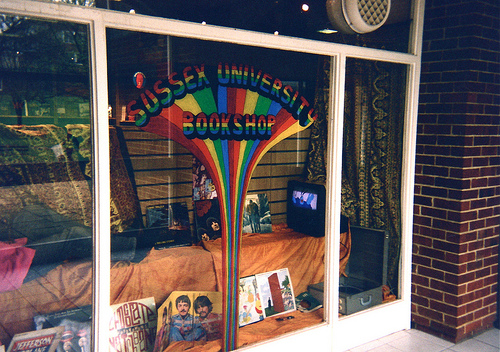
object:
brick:
[432, 132, 476, 148]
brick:
[452, 77, 487, 92]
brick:
[415, 260, 448, 280]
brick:
[410, 232, 434, 247]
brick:
[413, 301, 445, 322]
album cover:
[193, 197, 222, 244]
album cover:
[153, 290, 223, 350]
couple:
[246, 199, 260, 232]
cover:
[240, 192, 270, 234]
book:
[242, 192, 272, 236]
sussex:
[125, 64, 209, 128]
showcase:
[0, 3, 421, 351]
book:
[238, 264, 299, 327]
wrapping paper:
[123, 54, 341, 311]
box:
[306, 226, 390, 315]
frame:
[371, 34, 423, 253]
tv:
[284, 178, 325, 238]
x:
[193, 63, 214, 89]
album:
[151, 290, 231, 352]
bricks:
[458, 59, 496, 75]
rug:
[1, 117, 145, 252]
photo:
[157, 294, 227, 349]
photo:
[255, 267, 296, 319]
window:
[336, 53, 405, 318]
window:
[100, 21, 330, 350]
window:
[29, 0, 415, 53]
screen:
[293, 190, 316, 209]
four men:
[155, 293, 223, 349]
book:
[153, 280, 227, 352]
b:
[181, 111, 195, 136]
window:
[0, 11, 95, 351]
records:
[234, 266, 295, 328]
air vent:
[340, 0, 394, 35]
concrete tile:
[383, 327, 449, 351]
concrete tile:
[440, 334, 496, 351]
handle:
[360, 295, 372, 306]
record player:
[308, 224, 391, 315]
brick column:
[408, 1, 498, 343]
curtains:
[305, 63, 400, 231]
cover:
[145, 203, 192, 249]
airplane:
[5, 327, 62, 349]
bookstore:
[0, 0, 425, 352]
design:
[117, 53, 322, 350]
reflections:
[0, 51, 97, 256]